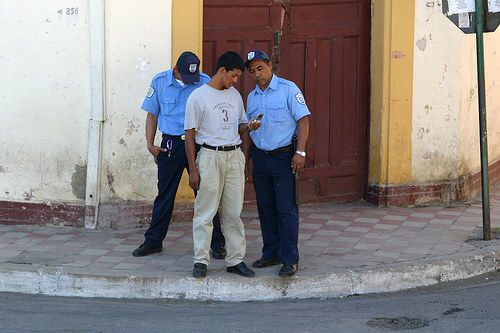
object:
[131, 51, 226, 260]
man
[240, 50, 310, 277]
man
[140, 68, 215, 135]
shirt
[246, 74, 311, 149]
shirt